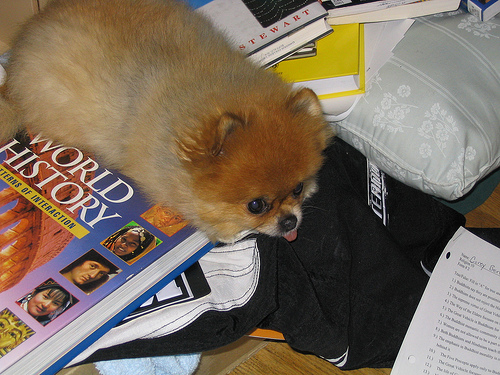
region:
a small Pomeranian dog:
[43, 25, 340, 239]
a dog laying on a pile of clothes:
[47, 13, 332, 276]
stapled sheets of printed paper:
[405, 226, 495, 371]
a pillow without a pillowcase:
[366, 25, 496, 185]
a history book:
[15, 135, 195, 370]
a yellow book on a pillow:
[277, 25, 377, 87]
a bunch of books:
[221, 0, 496, 45]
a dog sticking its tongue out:
[180, 97, 337, 252]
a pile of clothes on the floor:
[180, 186, 438, 361]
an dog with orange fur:
[43, 12, 340, 244]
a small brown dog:
[0, 0, 335, 240]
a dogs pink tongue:
[285, 231, 297, 243]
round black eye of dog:
[245, 198, 267, 215]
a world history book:
[1, 109, 218, 374]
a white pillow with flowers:
[332, 0, 499, 200]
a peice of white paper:
[390, 226, 496, 374]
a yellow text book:
[255, 16, 366, 102]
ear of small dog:
[282, 88, 326, 124]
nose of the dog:
[278, 216, 298, 231]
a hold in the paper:
[441, 249, 456, 262]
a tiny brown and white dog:
[5, 4, 335, 245]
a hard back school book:
[14, 113, 228, 355]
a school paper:
[389, 210, 499, 365]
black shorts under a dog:
[65, 152, 470, 356]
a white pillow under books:
[321, 10, 499, 192]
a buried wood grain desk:
[186, 182, 493, 373]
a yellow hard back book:
[248, 0, 377, 121]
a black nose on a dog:
[280, 216, 298, 230]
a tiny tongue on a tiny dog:
[282, 225, 300, 243]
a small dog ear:
[209, 104, 246, 154]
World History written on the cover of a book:
[3, 124, 138, 231]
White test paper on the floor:
[431, 221, 498, 369]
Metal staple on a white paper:
[450, 225, 466, 243]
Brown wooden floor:
[229, 340, 389, 373]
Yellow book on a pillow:
[282, 11, 367, 108]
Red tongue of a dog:
[281, 225, 301, 242]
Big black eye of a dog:
[244, 195, 267, 215]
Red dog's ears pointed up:
[195, 87, 325, 142]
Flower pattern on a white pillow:
[375, 80, 420, 140]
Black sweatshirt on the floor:
[279, 163, 450, 366]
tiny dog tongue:
[280, 228, 302, 245]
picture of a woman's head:
[96, 219, 162, 264]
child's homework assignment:
[390, 219, 499, 374]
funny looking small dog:
[0, 0, 337, 262]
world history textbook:
[0, 111, 222, 374]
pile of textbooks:
[191, 0, 499, 94]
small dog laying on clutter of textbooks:
[3, 0, 498, 374]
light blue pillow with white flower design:
[359, 17, 499, 207]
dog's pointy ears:
[178, 84, 328, 158]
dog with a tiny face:
[191, 85, 335, 247]